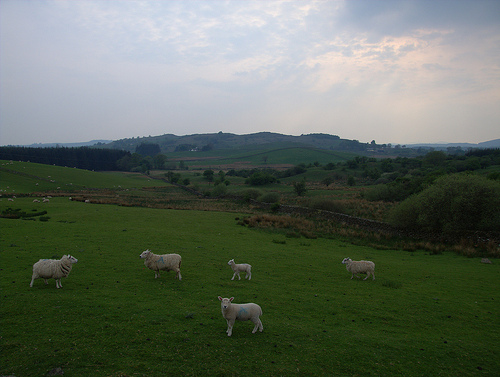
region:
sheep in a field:
[103, 207, 360, 375]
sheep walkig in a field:
[69, 193, 318, 370]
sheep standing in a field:
[21, 211, 447, 372]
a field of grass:
[107, 227, 307, 369]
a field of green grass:
[43, 194, 439, 375]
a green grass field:
[79, 211, 365, 373]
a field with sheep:
[33, 197, 418, 374]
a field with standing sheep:
[64, 218, 402, 375]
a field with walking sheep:
[32, 205, 482, 373]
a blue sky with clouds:
[58, 20, 361, 82]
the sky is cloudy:
[127, 25, 453, 207]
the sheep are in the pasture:
[159, 258, 270, 361]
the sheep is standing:
[183, 296, 298, 366]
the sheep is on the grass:
[262, 295, 474, 342]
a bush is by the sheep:
[247, 192, 377, 340]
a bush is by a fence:
[237, 180, 495, 349]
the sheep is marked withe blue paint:
[208, 283, 276, 353]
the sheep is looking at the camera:
[210, 295, 262, 334]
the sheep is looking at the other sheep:
[27, 250, 184, 340]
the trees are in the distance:
[293, 143, 478, 315]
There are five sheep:
[16, 246, 377, 336]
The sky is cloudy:
[0, 0, 496, 147]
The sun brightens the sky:
[5, 0, 490, 132]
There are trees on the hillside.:
[170, 140, 496, 242]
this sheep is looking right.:
[18, 232, 103, 298]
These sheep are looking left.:
[132, 235, 388, 336]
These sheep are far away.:
[0, 167, 170, 222]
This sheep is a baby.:
[216, 250, 261, 290]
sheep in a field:
[142, 208, 414, 365]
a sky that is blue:
[160, 16, 414, 143]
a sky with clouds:
[154, 27, 344, 121]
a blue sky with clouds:
[139, 19, 297, 90]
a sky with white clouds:
[165, 1, 377, 140]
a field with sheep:
[33, 204, 418, 359]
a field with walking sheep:
[79, 193, 432, 373]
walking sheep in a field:
[43, 209, 397, 369]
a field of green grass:
[68, 223, 489, 367]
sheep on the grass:
[83, 189, 371, 371]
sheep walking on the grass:
[111, 191, 381, 368]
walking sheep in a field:
[53, 216, 313, 364]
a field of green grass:
[74, 208, 361, 362]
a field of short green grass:
[90, 211, 492, 368]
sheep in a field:
[58, 203, 411, 371]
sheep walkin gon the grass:
[52, 215, 439, 375]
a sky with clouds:
[208, 31, 488, 104]